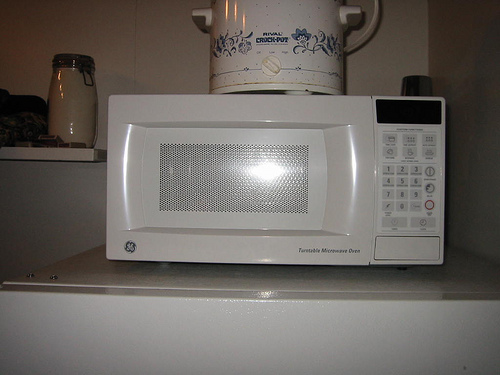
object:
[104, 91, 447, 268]
microwave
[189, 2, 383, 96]
crockpot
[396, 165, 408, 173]
number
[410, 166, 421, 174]
number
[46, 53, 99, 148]
jar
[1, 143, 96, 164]
shelf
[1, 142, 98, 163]
counter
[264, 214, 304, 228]
oven plastic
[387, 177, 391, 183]
number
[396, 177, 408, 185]
button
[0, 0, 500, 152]
wall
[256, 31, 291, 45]
word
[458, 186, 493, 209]
part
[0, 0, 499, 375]
kitchen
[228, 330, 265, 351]
part